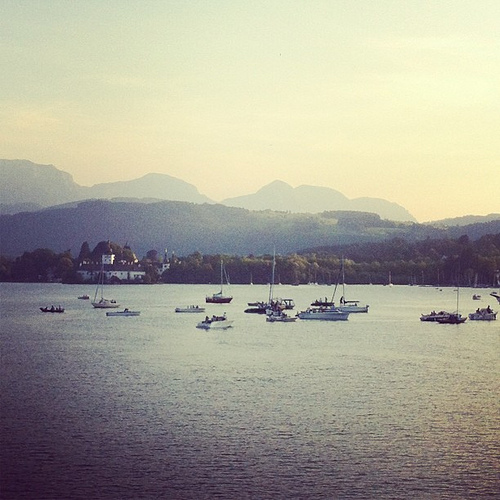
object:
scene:
[6, 4, 498, 496]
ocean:
[0, 282, 498, 499]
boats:
[37, 282, 500, 332]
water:
[6, 280, 493, 498]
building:
[73, 240, 149, 285]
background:
[12, 240, 499, 280]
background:
[0, 158, 499, 289]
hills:
[0, 158, 500, 284]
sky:
[4, 5, 498, 194]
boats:
[175, 292, 370, 328]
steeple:
[102, 238, 114, 256]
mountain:
[0, 158, 418, 224]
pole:
[213, 258, 225, 298]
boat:
[205, 292, 233, 303]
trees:
[282, 249, 354, 276]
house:
[70, 236, 155, 285]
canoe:
[39, 305, 65, 314]